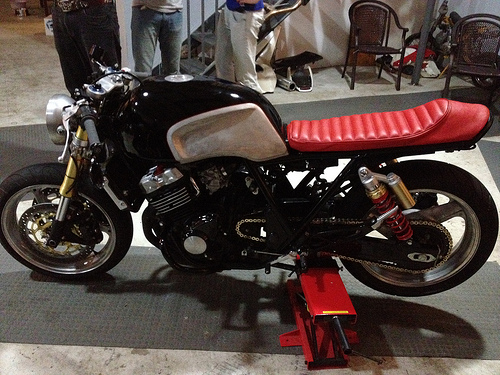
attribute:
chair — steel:
[338, 24, 433, 88]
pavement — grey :
[4, 337, 499, 372]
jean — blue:
[136, 7, 196, 109]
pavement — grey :
[1, 4, 498, 374]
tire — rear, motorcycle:
[327, 157, 498, 301]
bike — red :
[11, 51, 497, 318]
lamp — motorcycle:
[40, 87, 92, 150]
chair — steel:
[338, 0, 410, 92]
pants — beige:
[214, 4, 265, 94]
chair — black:
[339, 4, 411, 99]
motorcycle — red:
[1, 42, 499, 301]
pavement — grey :
[25, 280, 207, 373]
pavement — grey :
[141, 347, 295, 374]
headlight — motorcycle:
[46, 92, 76, 146]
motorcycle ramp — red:
[281, 250, 361, 366]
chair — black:
[448, 53, 494, 94]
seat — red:
[282, 84, 490, 172]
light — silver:
[32, 79, 79, 142]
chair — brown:
[447, 59, 498, 105]